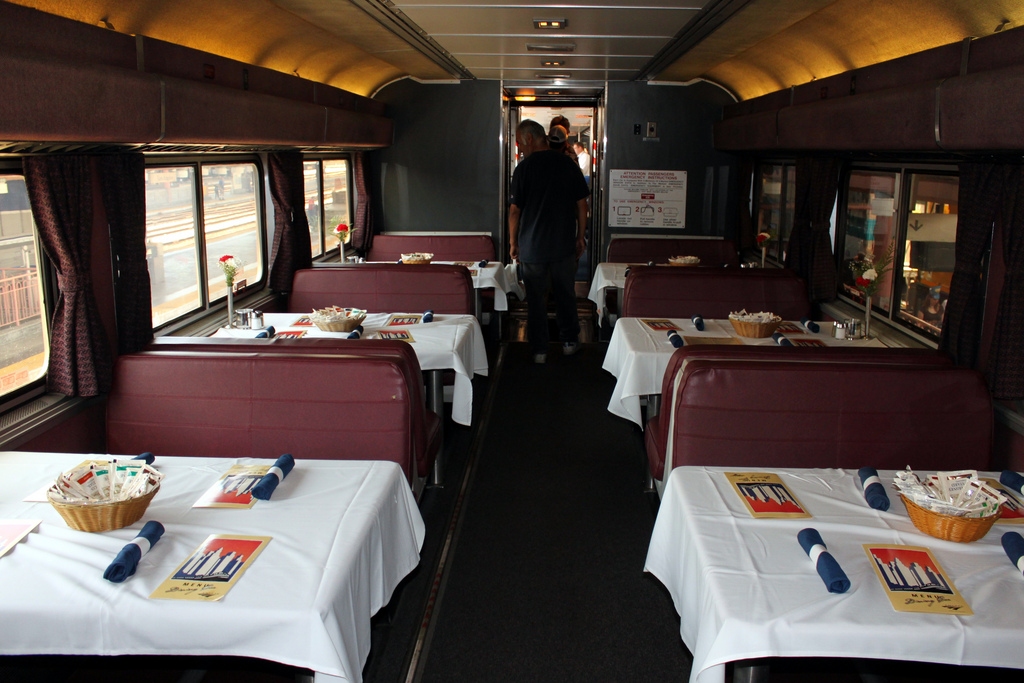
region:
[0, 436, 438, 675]
The made up table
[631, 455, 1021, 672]
A made up table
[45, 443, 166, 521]
The wicker basket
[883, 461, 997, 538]
A wicker basket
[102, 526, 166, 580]
The blue napkin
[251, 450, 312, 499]
A blue napkin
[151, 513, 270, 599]
The yellow menu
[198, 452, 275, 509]
A yellow menu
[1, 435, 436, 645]
The white table cloth on the table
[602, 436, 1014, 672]
A white table cloth on the table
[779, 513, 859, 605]
silverware rolled in a blue napkin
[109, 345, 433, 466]
a red bench seat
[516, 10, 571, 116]
lights on the ceiling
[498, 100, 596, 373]
people walking down the isle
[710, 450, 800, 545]
menus on the table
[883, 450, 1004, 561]
a wicker basket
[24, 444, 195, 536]
a basket on top of the table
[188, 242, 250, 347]
a rose in the vase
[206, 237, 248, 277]
a red rose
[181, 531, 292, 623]
the menus are yellow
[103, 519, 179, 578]
the napkin is blue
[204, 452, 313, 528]
napkin beside the menu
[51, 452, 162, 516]
packets in the basket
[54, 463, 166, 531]
basket is on the table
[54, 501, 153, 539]
the basket is woven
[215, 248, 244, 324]
flowers in the vase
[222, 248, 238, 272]
the flower is orange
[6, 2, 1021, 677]
passenger train car with booths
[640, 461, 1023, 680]
dining table in passenger train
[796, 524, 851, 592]
blue fabric napkin rolled up on table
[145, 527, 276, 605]
menu sitting on dining table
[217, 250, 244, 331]
red flower is in a vase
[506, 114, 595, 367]
workers standing in a passenger train car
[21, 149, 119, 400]
red and black curtains are open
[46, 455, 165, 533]
wicker basket on table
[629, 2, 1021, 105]
overhead lights in train car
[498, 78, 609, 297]
doorway to another train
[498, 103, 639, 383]
People lurking in the isles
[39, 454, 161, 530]
A basket of condiments on a table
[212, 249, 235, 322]
Flowers in a vase on a table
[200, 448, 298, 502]
A menu and rolled napkin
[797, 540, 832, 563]
A white ring around a napkin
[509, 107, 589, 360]
A man standing in a train doorway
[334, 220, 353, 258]
A red flower in a vase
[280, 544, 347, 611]
the cloth is white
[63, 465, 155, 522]
a basket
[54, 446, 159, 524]
the basket is brown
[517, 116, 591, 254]
people standing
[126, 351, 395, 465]
the back of the seats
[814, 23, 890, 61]
a light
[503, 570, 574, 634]
the carpet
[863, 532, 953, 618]
a brochure on the table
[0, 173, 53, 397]
train window next to table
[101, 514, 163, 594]
a rolled up table cloth in blue color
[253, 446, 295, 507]
a rolled up table cloth in blue color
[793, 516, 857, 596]
a rolled up table cloth in blue color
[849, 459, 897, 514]
a rolled up table cloth in blue color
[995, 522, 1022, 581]
a rolled up table cloth in blue color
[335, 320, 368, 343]
a rolled up table cloth in blue color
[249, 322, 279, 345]
a rolled up table cloth in blue color